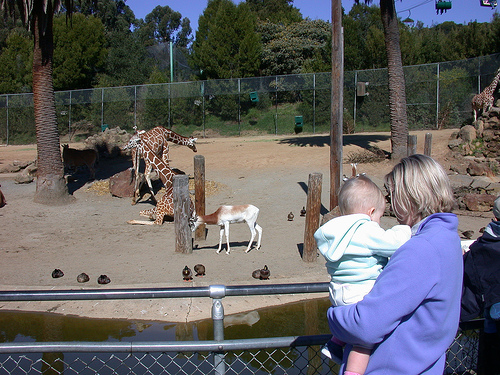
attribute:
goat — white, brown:
[178, 196, 277, 259]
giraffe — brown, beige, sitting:
[123, 140, 198, 231]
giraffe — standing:
[130, 115, 200, 205]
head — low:
[170, 125, 210, 157]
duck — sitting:
[91, 265, 126, 288]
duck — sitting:
[74, 268, 93, 286]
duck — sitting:
[40, 266, 72, 279]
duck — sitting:
[248, 262, 279, 289]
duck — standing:
[180, 262, 197, 282]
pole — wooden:
[325, 5, 351, 217]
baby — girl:
[311, 169, 412, 305]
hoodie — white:
[315, 208, 406, 274]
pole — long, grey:
[428, 59, 444, 135]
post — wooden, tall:
[317, 1, 350, 218]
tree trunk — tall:
[18, 13, 80, 207]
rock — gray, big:
[80, 124, 152, 164]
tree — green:
[205, 5, 271, 116]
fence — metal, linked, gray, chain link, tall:
[0, 46, 496, 149]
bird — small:
[282, 213, 302, 222]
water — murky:
[5, 295, 380, 373]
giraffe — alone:
[467, 58, 499, 145]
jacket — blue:
[317, 201, 480, 374]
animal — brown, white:
[128, 133, 210, 234]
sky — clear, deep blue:
[71, 1, 490, 55]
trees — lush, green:
[3, 12, 474, 102]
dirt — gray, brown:
[36, 242, 131, 256]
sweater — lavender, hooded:
[335, 208, 476, 372]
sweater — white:
[314, 213, 409, 310]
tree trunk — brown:
[161, 156, 198, 263]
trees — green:
[54, 8, 499, 167]